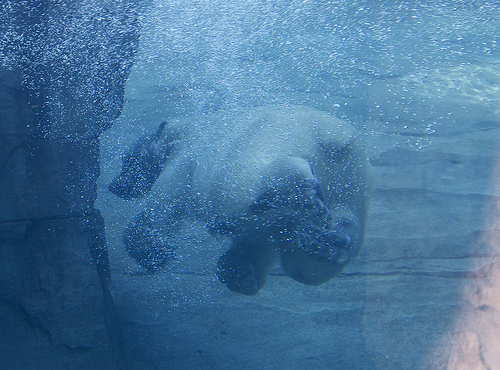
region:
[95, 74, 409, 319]
Polar bear in the water.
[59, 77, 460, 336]
Bear under the water.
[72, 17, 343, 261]
Bubbles in the water.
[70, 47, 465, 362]
Rocks under the water.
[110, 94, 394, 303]
Blue water with bear.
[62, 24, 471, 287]
Deep water with the bear.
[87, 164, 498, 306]
Four legs on the bear.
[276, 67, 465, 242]
Tail on the bear.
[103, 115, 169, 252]
Face of the bear.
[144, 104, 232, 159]
Ears on the bear.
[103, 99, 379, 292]
a polar bear swimming underwater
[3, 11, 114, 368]
a rock wall beside a polar bear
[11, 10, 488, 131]
bubbles from a swimming polar bear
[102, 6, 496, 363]
a rock wall in front of a swimming polar bear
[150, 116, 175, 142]
the ear of a polar bear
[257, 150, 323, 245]
the back paw on a polar bear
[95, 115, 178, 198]
the head of a polar bear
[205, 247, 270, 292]
the front right paw of a polar bear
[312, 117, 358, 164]
the tail of a polar bear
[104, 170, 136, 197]
the dark nose of a polar bear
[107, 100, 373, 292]
white polar bear swimming in water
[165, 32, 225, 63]
bubbles floating in the blue water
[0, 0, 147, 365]
stone wall in center of swimming hole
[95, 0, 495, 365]
stone wall on the outside of swimming hole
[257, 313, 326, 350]
clear blue clean water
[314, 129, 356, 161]
polar bear's white tail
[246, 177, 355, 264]
polar bear's back feet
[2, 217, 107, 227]
crack in stone on center wall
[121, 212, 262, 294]
polar bear's front paws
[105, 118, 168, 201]
white polar bear's big head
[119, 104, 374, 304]
bear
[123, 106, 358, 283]
white bear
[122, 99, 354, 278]
polar bear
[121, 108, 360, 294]
white polar bear swimming in tank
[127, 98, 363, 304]
polar bear creating bubbles white swimming in tank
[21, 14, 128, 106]
bubbles caused by polar bear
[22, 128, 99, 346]
gray rock formation in tank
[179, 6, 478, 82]
bubbles caused by white polar bear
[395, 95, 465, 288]
blue water in tank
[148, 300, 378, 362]
blue water in tank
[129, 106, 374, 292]
polar bear in water tank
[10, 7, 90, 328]
gray rock in tank with blue water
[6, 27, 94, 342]
gray rock in tank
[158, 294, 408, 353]
blue tinted water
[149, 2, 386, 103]
bubbles in blue tinted water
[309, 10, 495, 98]
bubbles in blue tinted water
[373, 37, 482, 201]
bubbles in blue tinted water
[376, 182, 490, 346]
bubbles in blue tinted water